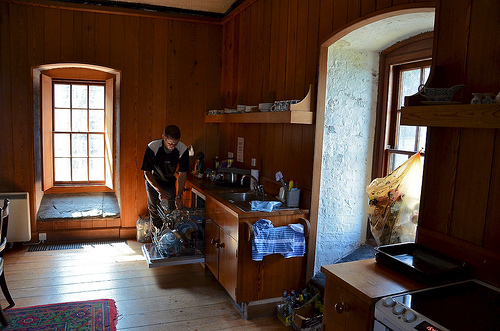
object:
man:
[141, 125, 189, 244]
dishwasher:
[140, 187, 205, 268]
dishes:
[158, 232, 182, 254]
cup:
[269, 100, 300, 112]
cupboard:
[205, 83, 313, 124]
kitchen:
[23, 6, 479, 253]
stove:
[373, 278, 499, 330]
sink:
[222, 191, 300, 212]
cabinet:
[207, 197, 306, 305]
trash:
[369, 188, 420, 246]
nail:
[422, 147, 424, 149]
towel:
[252, 218, 305, 261]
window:
[87, 84, 105, 110]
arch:
[30, 62, 124, 194]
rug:
[0, 298, 118, 331]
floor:
[5, 240, 237, 328]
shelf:
[400, 104, 499, 128]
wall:
[434, 132, 492, 226]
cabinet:
[320, 256, 438, 330]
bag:
[365, 149, 423, 247]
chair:
[0, 198, 16, 312]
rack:
[300, 217, 312, 238]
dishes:
[237, 105, 245, 108]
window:
[87, 157, 105, 184]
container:
[286, 188, 301, 208]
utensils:
[275, 171, 288, 191]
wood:
[46, 77, 53, 189]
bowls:
[259, 103, 273, 112]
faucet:
[241, 174, 265, 201]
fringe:
[112, 302, 120, 326]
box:
[293, 310, 324, 330]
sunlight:
[95, 244, 129, 259]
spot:
[37, 192, 121, 220]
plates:
[225, 111, 233, 114]